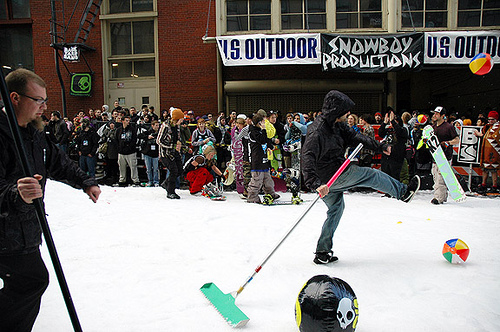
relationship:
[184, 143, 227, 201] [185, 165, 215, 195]
man wearing red pants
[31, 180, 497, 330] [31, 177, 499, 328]
snow covering ground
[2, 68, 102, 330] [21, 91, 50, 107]
man wearing glasses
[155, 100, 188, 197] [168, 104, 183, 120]
man wearing hat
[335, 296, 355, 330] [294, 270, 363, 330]
skull on ball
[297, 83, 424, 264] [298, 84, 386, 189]
man wearing jacket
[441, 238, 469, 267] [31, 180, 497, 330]
beach ball on snow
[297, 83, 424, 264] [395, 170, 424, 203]
man has foot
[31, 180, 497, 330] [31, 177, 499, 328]
snow on ground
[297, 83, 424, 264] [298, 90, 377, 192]
man wearing jacket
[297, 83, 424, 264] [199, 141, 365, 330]
man holding shovel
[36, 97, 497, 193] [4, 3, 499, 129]
crowd next to building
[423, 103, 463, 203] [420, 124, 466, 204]
man holding snowboard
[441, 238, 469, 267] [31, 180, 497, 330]
beach ball in snow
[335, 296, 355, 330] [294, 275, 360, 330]
skull on ball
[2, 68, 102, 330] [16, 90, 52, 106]
man wearing glasses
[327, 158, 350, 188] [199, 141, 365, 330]
tape on shovel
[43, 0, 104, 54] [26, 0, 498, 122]
ladder on building